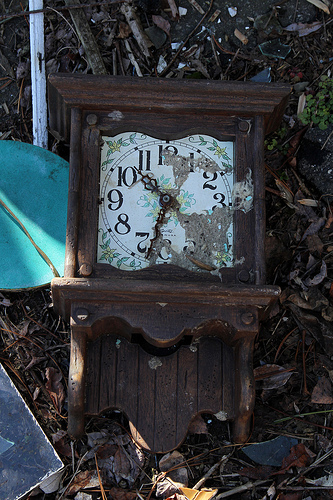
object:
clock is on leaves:
[97, 130, 237, 277]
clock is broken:
[98, 133, 235, 269]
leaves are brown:
[1, 36, 26, 84]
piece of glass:
[1, 363, 66, 497]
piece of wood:
[46, 72, 291, 448]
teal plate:
[0, 140, 70, 289]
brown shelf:
[47, 73, 288, 453]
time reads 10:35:
[124, 129, 176, 264]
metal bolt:
[236, 117, 251, 134]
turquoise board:
[50, 72, 293, 456]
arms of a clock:
[130, 161, 166, 209]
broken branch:
[2, 1, 125, 27]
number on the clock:
[115, 164, 138, 189]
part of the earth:
[3, 2, 328, 71]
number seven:
[133, 231, 153, 258]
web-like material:
[95, 128, 237, 272]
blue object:
[1, 139, 69, 292]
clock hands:
[144, 198, 170, 258]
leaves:
[83, 441, 116, 473]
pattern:
[176, 183, 211, 229]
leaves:
[315, 376, 332, 414]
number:
[135, 147, 151, 173]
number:
[106, 186, 123, 211]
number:
[111, 212, 129, 238]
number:
[133, 232, 151, 253]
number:
[156, 144, 175, 168]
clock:
[45, 68, 294, 456]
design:
[68, 397, 249, 452]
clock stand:
[45, 71, 293, 453]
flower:
[213, 144, 226, 157]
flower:
[107, 136, 120, 152]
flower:
[101, 243, 117, 256]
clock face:
[100, 130, 234, 274]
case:
[44, 68, 289, 453]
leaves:
[46, 349, 66, 414]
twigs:
[255, 397, 332, 428]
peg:
[74, 307, 89, 319]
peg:
[239, 308, 255, 324]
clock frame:
[44, 69, 292, 454]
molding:
[27, 2, 49, 151]